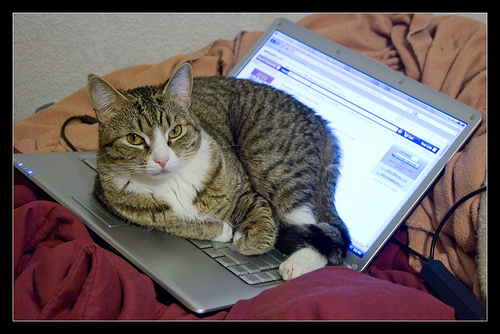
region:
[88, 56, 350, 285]
A cat on a laptop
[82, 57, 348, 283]
A cat on a laptop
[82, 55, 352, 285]
A cat on a laptop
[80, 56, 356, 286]
A cat on a laptop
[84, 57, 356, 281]
A cat on resting on a laptop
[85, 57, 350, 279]
A cat on resting on a laptop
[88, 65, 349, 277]
gray and white tabby cat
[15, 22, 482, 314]
cat laying on a laptop computer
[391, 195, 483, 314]
black power cord for latptop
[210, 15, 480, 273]
the laptop screen is on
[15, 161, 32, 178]
blue lights on the front of laptop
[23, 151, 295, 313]
silver laptop keyboard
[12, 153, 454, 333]
red comforter under laptop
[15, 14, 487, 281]
orange blanket under laptop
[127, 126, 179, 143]
the cat's green eyes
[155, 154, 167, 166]
the cat's pink nose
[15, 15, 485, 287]
brown blanket under computer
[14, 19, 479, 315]
open laptop on blankets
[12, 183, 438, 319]
red comforter under computer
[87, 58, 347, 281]
cat on top of keyboard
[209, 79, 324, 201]
stripes on cat fur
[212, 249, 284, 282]
buttons on top of keyboard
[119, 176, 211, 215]
white chest of cat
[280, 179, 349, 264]
tail wrapped around foot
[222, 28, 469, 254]
glowing image on screen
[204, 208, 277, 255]
paws tucked under body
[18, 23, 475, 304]
The cat sits on the laptop.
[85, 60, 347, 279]
The kitty curled up.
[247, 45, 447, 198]
The screen on the laptop.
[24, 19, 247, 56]
The carpet in the house.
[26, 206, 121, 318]
The blanket on the bed.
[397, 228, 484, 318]
The charger.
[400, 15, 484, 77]
Blankets on the bed.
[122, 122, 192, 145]
The cat's eyes.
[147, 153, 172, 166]
The cat's nose.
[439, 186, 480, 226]
The charging cord.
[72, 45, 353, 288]
a cat sitting on a laptop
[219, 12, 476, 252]
a laptop computer screen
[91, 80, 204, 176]
a cat's small head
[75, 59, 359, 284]
cat sitting on laptop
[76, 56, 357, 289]
cat on laptop is big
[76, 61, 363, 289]
cat on laptop is brown